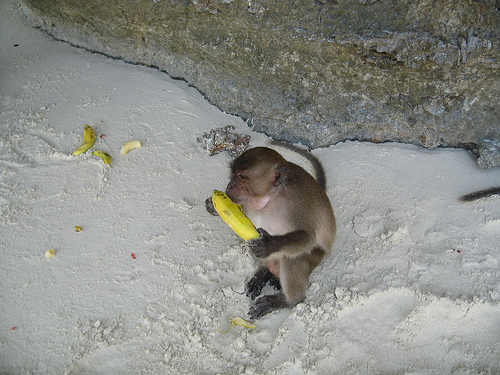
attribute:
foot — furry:
[247, 291, 289, 319]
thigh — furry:
[271, 258, 319, 306]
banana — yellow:
[212, 188, 262, 245]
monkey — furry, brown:
[205, 131, 340, 321]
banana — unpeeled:
[204, 180, 272, 245]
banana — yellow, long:
[205, 191, 267, 258]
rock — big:
[326, 18, 473, 135]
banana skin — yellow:
[226, 315, 256, 332]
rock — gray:
[359, 123, 374, 154]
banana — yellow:
[209, 183, 263, 242]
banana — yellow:
[206, 182, 267, 249]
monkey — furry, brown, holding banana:
[218, 148, 338, 311]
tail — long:
[267, 135, 334, 189]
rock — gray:
[133, 0, 455, 155]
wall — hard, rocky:
[121, 19, 455, 194]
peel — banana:
[72, 123, 112, 165]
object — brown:
[193, 122, 250, 166]